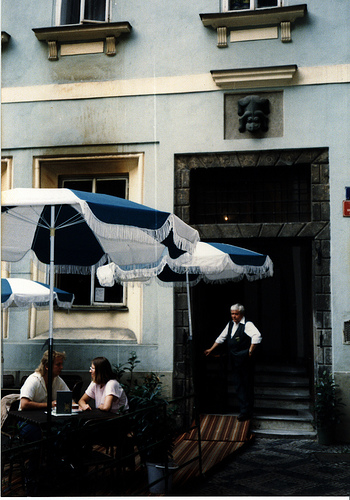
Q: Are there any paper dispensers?
A: No, there are no paper dispensers.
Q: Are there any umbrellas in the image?
A: Yes, there is an umbrella.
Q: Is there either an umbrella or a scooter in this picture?
A: Yes, there is an umbrella.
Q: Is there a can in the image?
A: No, there are no cans.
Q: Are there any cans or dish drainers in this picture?
A: No, there are no cans or dish drainers.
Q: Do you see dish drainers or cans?
A: No, there are no cans or dish drainers.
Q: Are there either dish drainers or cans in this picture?
A: No, there are no cans or dish drainers.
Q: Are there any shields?
A: No, there are no shields.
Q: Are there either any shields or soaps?
A: No, there are no shields or soaps.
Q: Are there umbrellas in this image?
A: Yes, there is an umbrella.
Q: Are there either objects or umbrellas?
A: Yes, there is an umbrella.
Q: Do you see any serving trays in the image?
A: No, there are no serving trays.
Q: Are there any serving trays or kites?
A: No, there are no serving trays or kites.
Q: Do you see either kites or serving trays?
A: No, there are no serving trays or kites.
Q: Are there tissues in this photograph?
A: No, there are no tissues.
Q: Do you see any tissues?
A: No, there are no tissues.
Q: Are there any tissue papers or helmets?
A: No, there are no tissue papers or helmets.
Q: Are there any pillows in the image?
A: No, there are no pillows.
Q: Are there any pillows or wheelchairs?
A: No, there are no pillows or wheelchairs.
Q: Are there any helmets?
A: No, there are no helmets.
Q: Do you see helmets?
A: No, there are no helmets.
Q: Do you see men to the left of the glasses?
A: Yes, there is a man to the left of the glasses.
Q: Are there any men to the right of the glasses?
A: No, the man is to the left of the glasses.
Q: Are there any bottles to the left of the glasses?
A: No, there is a man to the left of the glasses.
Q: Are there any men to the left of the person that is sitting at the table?
A: Yes, there is a man to the left of the person.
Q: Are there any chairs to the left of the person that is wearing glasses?
A: No, there is a man to the left of the person.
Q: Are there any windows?
A: Yes, there is a window.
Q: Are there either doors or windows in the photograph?
A: Yes, there is a window.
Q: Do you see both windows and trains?
A: No, there is a window but no trains.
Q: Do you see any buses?
A: No, there are no buses.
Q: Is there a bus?
A: No, there are no buses.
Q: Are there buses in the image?
A: No, there are no buses.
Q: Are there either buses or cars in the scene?
A: No, there are no buses or cars.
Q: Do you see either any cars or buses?
A: No, there are no buses or cars.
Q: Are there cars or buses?
A: No, there are no buses or cars.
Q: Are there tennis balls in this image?
A: No, there are no tennis balls.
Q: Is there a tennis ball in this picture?
A: No, there are no tennis balls.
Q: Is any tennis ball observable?
A: No, there are no tennis balls.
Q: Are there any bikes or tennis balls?
A: No, there are no tennis balls or bikes.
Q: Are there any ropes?
A: No, there are no ropes.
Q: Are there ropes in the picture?
A: No, there are no ropes.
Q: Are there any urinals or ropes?
A: No, there are no ropes or urinals.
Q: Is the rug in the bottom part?
A: Yes, the rug is in the bottom of the image.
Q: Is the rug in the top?
A: No, the rug is in the bottom of the image.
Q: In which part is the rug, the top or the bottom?
A: The rug is in the bottom of the image.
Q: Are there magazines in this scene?
A: No, there are no magazines.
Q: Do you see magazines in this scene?
A: No, there are no magazines.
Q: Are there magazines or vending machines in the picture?
A: No, there are no magazines or vending machines.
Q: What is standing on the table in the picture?
A: The menu is standing on the table.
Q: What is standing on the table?
A: The menu is standing on the table.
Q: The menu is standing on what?
A: The menu is standing on the table.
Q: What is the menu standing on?
A: The menu is standing on the table.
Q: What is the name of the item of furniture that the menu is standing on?
A: The piece of furniture is a table.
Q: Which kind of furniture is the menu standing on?
A: The menu is standing on the table.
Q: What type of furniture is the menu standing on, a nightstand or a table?
A: The menu is standing on a table.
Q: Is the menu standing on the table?
A: Yes, the menu is standing on the table.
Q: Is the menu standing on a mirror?
A: No, the menu is standing on the table.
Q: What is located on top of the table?
A: The menu is on top of the table.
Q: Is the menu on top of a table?
A: Yes, the menu is on top of a table.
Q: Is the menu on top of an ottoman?
A: No, the menu is on top of a table.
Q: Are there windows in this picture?
A: Yes, there is a window.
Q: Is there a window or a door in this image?
A: Yes, there is a window.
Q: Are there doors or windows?
A: Yes, there is a window.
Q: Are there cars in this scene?
A: No, there are no cars.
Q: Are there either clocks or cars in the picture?
A: No, there are no cars or clocks.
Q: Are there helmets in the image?
A: No, there are no helmets.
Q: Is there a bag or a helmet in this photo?
A: No, there are no helmets or bags.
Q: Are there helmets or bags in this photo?
A: No, there are no helmets or bags.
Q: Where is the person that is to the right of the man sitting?
A: The person is sitting at the table.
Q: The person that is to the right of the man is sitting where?
A: The person is sitting at the table.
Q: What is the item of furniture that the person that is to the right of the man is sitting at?
A: The piece of furniture is a table.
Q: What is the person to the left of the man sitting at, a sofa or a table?
A: The person is sitting at a table.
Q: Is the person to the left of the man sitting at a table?
A: Yes, the person is sitting at a table.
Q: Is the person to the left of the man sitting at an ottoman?
A: No, the person is sitting at a table.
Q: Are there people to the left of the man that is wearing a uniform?
A: Yes, there is a person to the left of the man.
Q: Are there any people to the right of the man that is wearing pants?
A: No, the person is to the left of the man.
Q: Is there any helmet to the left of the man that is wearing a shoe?
A: No, there is a person to the left of the man.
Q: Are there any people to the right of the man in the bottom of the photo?
A: Yes, there is a person to the right of the man.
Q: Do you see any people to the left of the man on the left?
A: No, the person is to the right of the man.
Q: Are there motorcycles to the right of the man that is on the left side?
A: No, there is a person to the right of the man.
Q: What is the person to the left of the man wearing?
A: The person is wearing glasses.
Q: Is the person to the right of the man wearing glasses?
A: Yes, the person is wearing glasses.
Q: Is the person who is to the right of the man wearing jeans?
A: No, the person is wearing glasses.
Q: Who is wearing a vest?
A: The man is wearing a vest.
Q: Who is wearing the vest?
A: The man is wearing a vest.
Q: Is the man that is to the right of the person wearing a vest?
A: Yes, the man is wearing a vest.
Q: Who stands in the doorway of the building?
A: The man stands in the doorway.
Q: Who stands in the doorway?
A: The man stands in the doorway.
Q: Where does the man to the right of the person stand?
A: The man stands in the doorway.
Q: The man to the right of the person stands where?
A: The man stands in the doorway.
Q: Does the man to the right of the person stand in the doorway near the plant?
A: Yes, the man stands in the doorway.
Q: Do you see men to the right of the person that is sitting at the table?
A: Yes, there is a man to the right of the person.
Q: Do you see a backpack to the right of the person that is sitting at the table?
A: No, there is a man to the right of the person.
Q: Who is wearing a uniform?
A: The man is wearing a uniform.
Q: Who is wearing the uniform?
A: The man is wearing a uniform.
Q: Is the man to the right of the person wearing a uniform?
A: Yes, the man is wearing a uniform.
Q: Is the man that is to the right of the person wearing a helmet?
A: No, the man is wearing a uniform.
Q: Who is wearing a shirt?
A: The man is wearing a shirt.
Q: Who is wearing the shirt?
A: The man is wearing a shirt.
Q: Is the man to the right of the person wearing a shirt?
A: Yes, the man is wearing a shirt.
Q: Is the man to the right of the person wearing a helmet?
A: No, the man is wearing a shirt.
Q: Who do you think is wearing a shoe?
A: The man is wearing a shoe.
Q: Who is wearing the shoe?
A: The man is wearing a shoe.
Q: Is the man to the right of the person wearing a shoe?
A: Yes, the man is wearing a shoe.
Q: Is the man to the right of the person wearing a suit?
A: No, the man is wearing a shoe.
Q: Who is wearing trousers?
A: The man is wearing trousers.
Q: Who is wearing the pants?
A: The man is wearing trousers.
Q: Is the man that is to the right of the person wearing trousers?
A: Yes, the man is wearing trousers.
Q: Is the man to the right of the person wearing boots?
A: No, the man is wearing trousers.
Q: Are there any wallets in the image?
A: No, there are no wallets.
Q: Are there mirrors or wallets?
A: No, there are no wallets or mirrors.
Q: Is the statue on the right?
A: Yes, the statue is on the right of the image.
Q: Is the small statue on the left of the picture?
A: No, the statue is on the right of the image.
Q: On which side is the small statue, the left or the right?
A: The statue is on the right of the image.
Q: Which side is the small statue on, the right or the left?
A: The statue is on the right of the image.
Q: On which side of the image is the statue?
A: The statue is on the right of the image.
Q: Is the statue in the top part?
A: Yes, the statue is in the top of the image.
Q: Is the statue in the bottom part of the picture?
A: No, the statue is in the top of the image.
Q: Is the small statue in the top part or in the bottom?
A: The statue is in the top of the image.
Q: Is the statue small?
A: Yes, the statue is small.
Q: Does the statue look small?
A: Yes, the statue is small.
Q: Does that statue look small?
A: Yes, the statue is small.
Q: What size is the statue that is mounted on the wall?
A: The statue is small.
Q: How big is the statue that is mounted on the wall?
A: The statue is small.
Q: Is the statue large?
A: No, the statue is small.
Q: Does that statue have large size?
A: No, the statue is small.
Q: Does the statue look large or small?
A: The statue is small.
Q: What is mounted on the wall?
A: The statue is mounted on the wall.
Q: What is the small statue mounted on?
A: The statue is mounted on the wall.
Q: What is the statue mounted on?
A: The statue is mounted on the wall.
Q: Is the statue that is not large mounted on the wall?
A: Yes, the statue is mounted on the wall.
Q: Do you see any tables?
A: Yes, there is a table.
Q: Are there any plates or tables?
A: Yes, there is a table.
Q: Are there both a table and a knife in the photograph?
A: No, there is a table but no knives.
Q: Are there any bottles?
A: No, there are no bottles.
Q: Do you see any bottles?
A: No, there are no bottles.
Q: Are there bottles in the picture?
A: No, there are no bottles.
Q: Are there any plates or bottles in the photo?
A: No, there are no bottles or plates.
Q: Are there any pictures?
A: No, there are no pictures.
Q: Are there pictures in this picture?
A: No, there are no pictures.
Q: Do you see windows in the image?
A: Yes, there is a window.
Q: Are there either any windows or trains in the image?
A: Yes, there is a window.